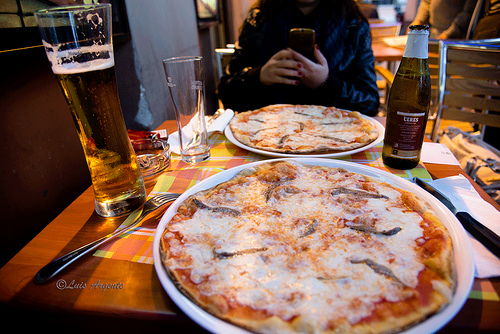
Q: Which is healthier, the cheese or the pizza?
A: The cheese is healthier than the pizza.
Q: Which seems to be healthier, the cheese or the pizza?
A: The cheese is healthier than the pizza.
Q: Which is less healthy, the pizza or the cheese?
A: The pizza is less healthy than the cheese.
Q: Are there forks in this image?
A: Yes, there is a fork.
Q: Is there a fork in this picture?
A: Yes, there is a fork.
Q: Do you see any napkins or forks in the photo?
A: Yes, there is a fork.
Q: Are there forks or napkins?
A: Yes, there is a fork.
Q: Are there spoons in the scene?
A: No, there are no spoons.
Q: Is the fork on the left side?
A: Yes, the fork is on the left of the image.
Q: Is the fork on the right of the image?
A: No, the fork is on the left of the image.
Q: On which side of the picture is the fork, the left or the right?
A: The fork is on the left of the image.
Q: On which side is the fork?
A: The fork is on the left of the image.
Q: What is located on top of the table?
A: The fork is on top of the table.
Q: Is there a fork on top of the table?
A: Yes, there is a fork on top of the table.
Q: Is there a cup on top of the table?
A: No, there is a fork on top of the table.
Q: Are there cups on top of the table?
A: No, there is a fork on top of the table.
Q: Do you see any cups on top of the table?
A: No, there is a fork on top of the table.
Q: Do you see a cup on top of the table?
A: No, there is a fork on top of the table.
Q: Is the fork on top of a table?
A: Yes, the fork is on top of a table.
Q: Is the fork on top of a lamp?
A: No, the fork is on top of a table.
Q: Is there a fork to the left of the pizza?
A: Yes, there is a fork to the left of the pizza.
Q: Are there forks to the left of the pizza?
A: Yes, there is a fork to the left of the pizza.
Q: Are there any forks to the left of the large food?
A: Yes, there is a fork to the left of the pizza.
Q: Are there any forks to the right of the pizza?
A: No, the fork is to the left of the pizza.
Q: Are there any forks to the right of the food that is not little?
A: No, the fork is to the left of the pizza.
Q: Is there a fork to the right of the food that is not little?
A: No, the fork is to the left of the pizza.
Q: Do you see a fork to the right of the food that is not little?
A: No, the fork is to the left of the pizza.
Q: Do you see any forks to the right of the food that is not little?
A: No, the fork is to the left of the pizza.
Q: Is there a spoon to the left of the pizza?
A: No, there is a fork to the left of the pizza.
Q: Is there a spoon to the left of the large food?
A: No, there is a fork to the left of the pizza.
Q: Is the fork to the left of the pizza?
A: Yes, the fork is to the left of the pizza.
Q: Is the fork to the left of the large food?
A: Yes, the fork is to the left of the pizza.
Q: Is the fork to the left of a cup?
A: No, the fork is to the left of the pizza.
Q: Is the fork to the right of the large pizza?
A: No, the fork is to the left of the pizza.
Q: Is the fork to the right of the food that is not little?
A: No, the fork is to the left of the pizza.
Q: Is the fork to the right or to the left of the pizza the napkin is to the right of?
A: The fork is to the left of the pizza.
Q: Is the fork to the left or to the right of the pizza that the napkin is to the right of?
A: The fork is to the left of the pizza.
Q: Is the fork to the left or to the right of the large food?
A: The fork is to the left of the pizza.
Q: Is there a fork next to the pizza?
A: Yes, there is a fork next to the pizza.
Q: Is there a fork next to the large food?
A: Yes, there is a fork next to the pizza.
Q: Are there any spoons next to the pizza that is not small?
A: No, there is a fork next to the pizza.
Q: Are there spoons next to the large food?
A: No, there is a fork next to the pizza.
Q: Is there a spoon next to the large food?
A: No, there is a fork next to the pizza.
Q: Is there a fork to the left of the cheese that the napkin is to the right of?
A: Yes, there is a fork to the left of the cheese.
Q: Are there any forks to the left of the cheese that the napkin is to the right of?
A: Yes, there is a fork to the left of the cheese.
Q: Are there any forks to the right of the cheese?
A: No, the fork is to the left of the cheese.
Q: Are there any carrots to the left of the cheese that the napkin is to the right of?
A: No, there is a fork to the left of the cheese.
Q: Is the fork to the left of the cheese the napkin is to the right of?
A: Yes, the fork is to the left of the cheese.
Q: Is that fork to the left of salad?
A: No, the fork is to the left of the cheese.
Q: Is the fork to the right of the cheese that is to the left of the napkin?
A: No, the fork is to the left of the cheese.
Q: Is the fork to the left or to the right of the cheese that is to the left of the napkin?
A: The fork is to the left of the cheese.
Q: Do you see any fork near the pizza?
A: Yes, there is a fork near the pizza.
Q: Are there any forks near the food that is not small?
A: Yes, there is a fork near the pizza.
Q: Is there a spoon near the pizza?
A: No, there is a fork near the pizza.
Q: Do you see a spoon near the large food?
A: No, there is a fork near the pizza.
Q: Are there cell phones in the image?
A: Yes, there is a cell phone.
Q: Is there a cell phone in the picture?
A: Yes, there is a cell phone.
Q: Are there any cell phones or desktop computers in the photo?
A: Yes, there is a cell phone.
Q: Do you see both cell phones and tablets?
A: No, there is a cell phone but no tablets.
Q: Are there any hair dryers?
A: No, there are no hair dryers.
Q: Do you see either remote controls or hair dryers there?
A: No, there are no hair dryers or remote controls.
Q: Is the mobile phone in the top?
A: Yes, the mobile phone is in the top of the image.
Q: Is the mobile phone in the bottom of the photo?
A: No, the mobile phone is in the top of the image.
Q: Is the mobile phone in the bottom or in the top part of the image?
A: The mobile phone is in the top of the image.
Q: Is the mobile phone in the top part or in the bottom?
A: The mobile phone is in the top of the image.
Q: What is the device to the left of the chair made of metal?
A: The device is a cell phone.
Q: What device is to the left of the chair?
A: The device is a cell phone.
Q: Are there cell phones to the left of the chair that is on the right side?
A: Yes, there is a cell phone to the left of the chair.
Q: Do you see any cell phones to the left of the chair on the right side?
A: Yes, there is a cell phone to the left of the chair.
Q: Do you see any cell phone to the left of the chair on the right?
A: Yes, there is a cell phone to the left of the chair.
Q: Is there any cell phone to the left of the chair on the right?
A: Yes, there is a cell phone to the left of the chair.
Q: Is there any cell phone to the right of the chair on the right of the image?
A: No, the cell phone is to the left of the chair.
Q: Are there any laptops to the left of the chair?
A: No, there is a cell phone to the left of the chair.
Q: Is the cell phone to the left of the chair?
A: Yes, the cell phone is to the left of the chair.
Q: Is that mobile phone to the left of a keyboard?
A: No, the mobile phone is to the left of the chair.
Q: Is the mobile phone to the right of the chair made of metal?
A: No, the mobile phone is to the left of the chair.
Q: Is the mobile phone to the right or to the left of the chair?
A: The mobile phone is to the left of the chair.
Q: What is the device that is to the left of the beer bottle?
A: The device is a cell phone.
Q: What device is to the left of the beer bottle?
A: The device is a cell phone.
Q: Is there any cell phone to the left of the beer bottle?
A: Yes, there is a cell phone to the left of the beer bottle.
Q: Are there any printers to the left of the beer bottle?
A: No, there is a cell phone to the left of the beer bottle.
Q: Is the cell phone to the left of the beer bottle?
A: Yes, the cell phone is to the left of the beer bottle.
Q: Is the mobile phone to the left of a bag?
A: No, the mobile phone is to the left of the beer bottle.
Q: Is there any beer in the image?
A: Yes, there is beer.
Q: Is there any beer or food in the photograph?
A: Yes, there is beer.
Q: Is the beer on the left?
A: Yes, the beer is on the left of the image.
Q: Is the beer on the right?
A: No, the beer is on the left of the image.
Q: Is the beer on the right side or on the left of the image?
A: The beer is on the left of the image.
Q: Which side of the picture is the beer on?
A: The beer is on the left of the image.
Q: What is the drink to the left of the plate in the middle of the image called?
A: The drink is beer.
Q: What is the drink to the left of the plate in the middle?
A: The drink is beer.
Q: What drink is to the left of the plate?
A: The drink is beer.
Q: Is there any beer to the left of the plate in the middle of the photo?
A: Yes, there is beer to the left of the plate.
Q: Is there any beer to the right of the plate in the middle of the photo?
A: No, the beer is to the left of the plate.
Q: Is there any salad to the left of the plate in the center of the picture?
A: No, there is beer to the left of the plate.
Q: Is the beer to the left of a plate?
A: Yes, the beer is to the left of a plate.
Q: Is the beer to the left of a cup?
A: No, the beer is to the left of a plate.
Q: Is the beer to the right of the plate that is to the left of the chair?
A: No, the beer is to the left of the plate.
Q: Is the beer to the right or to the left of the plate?
A: The beer is to the left of the plate.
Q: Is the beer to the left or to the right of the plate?
A: The beer is to the left of the plate.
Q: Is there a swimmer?
A: No, there are no swimmers.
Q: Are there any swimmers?
A: No, there are no swimmers.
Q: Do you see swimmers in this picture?
A: No, there are no swimmers.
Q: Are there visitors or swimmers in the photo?
A: No, there are no swimmers or visitors.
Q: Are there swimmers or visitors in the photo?
A: No, there are no swimmers or visitors.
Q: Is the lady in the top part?
A: Yes, the lady is in the top of the image.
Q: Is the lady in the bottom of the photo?
A: No, the lady is in the top of the image.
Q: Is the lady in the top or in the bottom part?
A: The lady is in the top of the image.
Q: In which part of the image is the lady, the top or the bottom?
A: The lady is in the top of the image.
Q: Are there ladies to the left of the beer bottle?
A: Yes, there is a lady to the left of the beer bottle.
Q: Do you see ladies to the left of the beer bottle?
A: Yes, there is a lady to the left of the beer bottle.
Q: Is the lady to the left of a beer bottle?
A: Yes, the lady is to the left of a beer bottle.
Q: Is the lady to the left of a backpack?
A: No, the lady is to the left of a beer bottle.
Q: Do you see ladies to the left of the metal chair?
A: Yes, there is a lady to the left of the chair.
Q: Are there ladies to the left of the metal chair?
A: Yes, there is a lady to the left of the chair.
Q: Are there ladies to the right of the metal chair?
A: No, the lady is to the left of the chair.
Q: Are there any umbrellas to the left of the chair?
A: No, there is a lady to the left of the chair.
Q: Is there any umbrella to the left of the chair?
A: No, there is a lady to the left of the chair.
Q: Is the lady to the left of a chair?
A: Yes, the lady is to the left of a chair.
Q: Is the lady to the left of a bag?
A: No, the lady is to the left of a chair.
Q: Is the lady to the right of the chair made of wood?
A: No, the lady is to the left of the chair.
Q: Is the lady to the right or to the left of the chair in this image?
A: The lady is to the left of the chair.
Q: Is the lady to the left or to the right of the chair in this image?
A: The lady is to the left of the chair.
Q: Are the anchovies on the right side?
A: Yes, the anchovies are on the right of the image.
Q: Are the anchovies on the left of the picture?
A: No, the anchovies are on the right of the image.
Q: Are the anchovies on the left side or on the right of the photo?
A: The anchovies are on the right of the image.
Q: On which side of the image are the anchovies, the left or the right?
A: The anchovies are on the right of the image.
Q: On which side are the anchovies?
A: The anchovies are on the right of the image.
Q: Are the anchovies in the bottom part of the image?
A: Yes, the anchovies are in the bottom of the image.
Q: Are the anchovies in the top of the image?
A: No, the anchovies are in the bottom of the image.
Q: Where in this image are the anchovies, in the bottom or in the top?
A: The anchovies are in the bottom of the image.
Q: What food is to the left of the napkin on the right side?
A: The food is anchovies.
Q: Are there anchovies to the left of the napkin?
A: Yes, there are anchovies to the left of the napkin.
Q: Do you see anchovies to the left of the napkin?
A: Yes, there are anchovies to the left of the napkin.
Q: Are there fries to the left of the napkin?
A: No, there are anchovies to the left of the napkin.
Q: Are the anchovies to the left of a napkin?
A: Yes, the anchovies are to the left of a napkin.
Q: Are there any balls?
A: No, there are no balls.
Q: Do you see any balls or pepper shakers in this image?
A: No, there are no balls or pepper shakers.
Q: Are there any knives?
A: Yes, there is a knife.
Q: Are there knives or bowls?
A: Yes, there is a knife.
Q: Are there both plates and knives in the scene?
A: Yes, there are both a knife and a plate.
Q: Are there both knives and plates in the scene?
A: Yes, there are both a knife and a plate.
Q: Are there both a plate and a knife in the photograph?
A: Yes, there are both a knife and a plate.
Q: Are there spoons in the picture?
A: No, there are no spoons.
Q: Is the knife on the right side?
A: Yes, the knife is on the right of the image.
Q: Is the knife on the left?
A: No, the knife is on the right of the image.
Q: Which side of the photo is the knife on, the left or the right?
A: The knife is on the right of the image.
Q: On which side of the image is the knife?
A: The knife is on the right of the image.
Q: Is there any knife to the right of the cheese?
A: Yes, there is a knife to the right of the cheese.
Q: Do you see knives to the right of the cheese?
A: Yes, there is a knife to the right of the cheese.